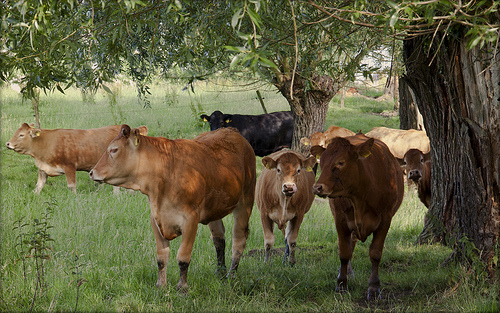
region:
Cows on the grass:
[5, 105, 440, 300]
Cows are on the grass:
[0, 105, 437, 300]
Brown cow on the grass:
[83, 122, 254, 297]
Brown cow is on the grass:
[84, 120, 262, 295]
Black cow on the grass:
[200, 107, 305, 156]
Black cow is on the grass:
[200, 109, 306, 157]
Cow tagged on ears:
[199, 111, 235, 125]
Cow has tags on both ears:
[196, 108, 233, 125]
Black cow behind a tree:
[197, 103, 303, 158]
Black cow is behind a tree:
[195, 107, 302, 155]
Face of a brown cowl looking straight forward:
[257, 146, 317, 198]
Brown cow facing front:
[257, 144, 317, 266]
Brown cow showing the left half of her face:
[309, 130, 404, 302]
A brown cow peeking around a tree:
[402, 140, 464, 245]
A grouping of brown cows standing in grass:
[87, 122, 417, 308]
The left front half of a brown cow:
[5, 118, 89, 191]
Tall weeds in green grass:
[6, 196, 61, 300]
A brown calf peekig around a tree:
[400, 125, 445, 242]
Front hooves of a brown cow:
[335, 270, 385, 302]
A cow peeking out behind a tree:
[398, 141, 450, 233]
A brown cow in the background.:
[3, 121, 150, 201]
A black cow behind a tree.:
[195, 104, 334, 157]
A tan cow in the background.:
[350, 112, 442, 155]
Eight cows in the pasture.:
[4, 97, 434, 292]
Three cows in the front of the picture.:
[89, 126, 403, 305]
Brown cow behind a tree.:
[398, 145, 498, 237]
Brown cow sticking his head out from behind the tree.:
[402, 146, 499, 247]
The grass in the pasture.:
[23, 225, 94, 311]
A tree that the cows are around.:
[218, 19, 379, 153]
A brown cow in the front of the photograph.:
[88, 125, 258, 298]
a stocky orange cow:
[92, 125, 259, 279]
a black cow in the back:
[199, 108, 294, 153]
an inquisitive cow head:
[397, 150, 433, 206]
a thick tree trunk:
[408, 0, 496, 297]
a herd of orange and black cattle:
[0, 93, 440, 295]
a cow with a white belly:
[256, 148, 316, 272]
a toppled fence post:
[253, 85, 269, 111]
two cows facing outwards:
[8, 120, 255, 285]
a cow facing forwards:
[252, 150, 314, 266]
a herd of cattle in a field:
[12, 103, 467, 291]